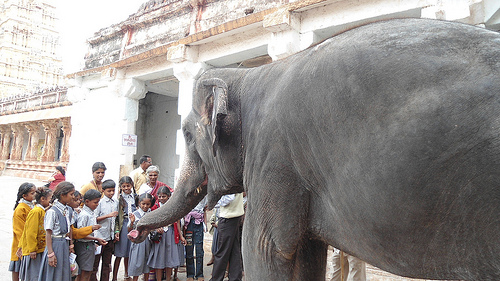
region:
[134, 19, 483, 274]
a very large elephant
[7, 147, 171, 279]
a group of school children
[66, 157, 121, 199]
a woman with black hair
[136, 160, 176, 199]
a woman with white hair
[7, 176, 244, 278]
children wearing school uniforms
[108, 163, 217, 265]
an elephant trunk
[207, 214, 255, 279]
a pair of dark gray slacks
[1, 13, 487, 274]
an old building with pillars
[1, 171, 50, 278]
girls wearing yellow jackets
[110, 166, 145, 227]
a girl with pigtails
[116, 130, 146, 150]
White sign on building above childen's heads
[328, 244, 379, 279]
Khaki pants under elephants belly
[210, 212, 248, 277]
Dark pants under elephants head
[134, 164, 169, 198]
Grey haired woman behind children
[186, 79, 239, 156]
Elephant ear facing camera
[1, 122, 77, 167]
Five discolored columns on left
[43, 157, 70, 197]
Dark haired woman sitting under columns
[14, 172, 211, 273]
Children playing with elephant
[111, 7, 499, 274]
Large elephant playing with children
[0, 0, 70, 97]
Large white building raising into sky on left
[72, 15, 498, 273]
school children feeding an elephant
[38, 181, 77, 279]
a young girl dressed in a gray and white school uniform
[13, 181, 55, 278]
2 young girls with yellow jackets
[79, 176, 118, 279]
2 school boys dressed in white shirts and gray pants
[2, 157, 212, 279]
a group of school children facing an elephant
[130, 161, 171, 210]
an older woman in the background dressed in red and white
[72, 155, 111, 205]
a woman dressed in yellow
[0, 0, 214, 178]
an old building in the background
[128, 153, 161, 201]
a man in the background wearing a light yellow shirt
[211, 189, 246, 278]
a man behind the elephant wearing dark gray slacks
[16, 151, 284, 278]
The kids are feeding the elephant.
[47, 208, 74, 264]
The child has on a blue uniform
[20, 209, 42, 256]
The little girl has on a yellow jacket.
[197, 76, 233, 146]
The elephant has a big ear.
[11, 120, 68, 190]
The columns on the building are rusting.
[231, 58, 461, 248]
The elephant is big and gray.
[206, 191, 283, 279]
A person is standing next to the elephant.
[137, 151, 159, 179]
The man is wearing glasses.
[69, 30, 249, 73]
The top of the building is dirty.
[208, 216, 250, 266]
The pants are black.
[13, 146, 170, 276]
Children looking at an elephant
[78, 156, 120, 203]
Woman with dark hair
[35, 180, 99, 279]
Girl in a gray dress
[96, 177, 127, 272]
Boy with dark hair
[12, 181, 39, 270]
Girl with dark hair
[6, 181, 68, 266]
Yellow sweater on a girl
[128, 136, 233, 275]
Trunk on an elephant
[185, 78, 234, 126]
Ear on an elephant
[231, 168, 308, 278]
Leg on an elephant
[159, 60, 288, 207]
Head on an elephant